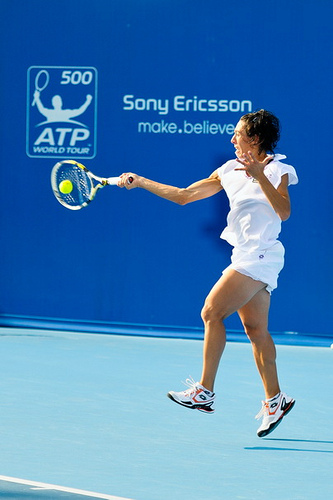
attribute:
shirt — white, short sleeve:
[204, 154, 290, 258]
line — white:
[0, 454, 126, 498]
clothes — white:
[211, 148, 300, 295]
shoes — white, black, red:
[166, 371, 293, 435]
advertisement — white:
[15, 58, 331, 175]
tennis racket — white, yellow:
[48, 156, 134, 212]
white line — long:
[1, 474, 146, 499]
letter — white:
[157, 97, 172, 117]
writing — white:
[25, 65, 250, 159]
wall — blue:
[1, 0, 332, 345]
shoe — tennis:
[164, 373, 217, 416]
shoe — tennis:
[252, 389, 297, 439]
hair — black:
[240, 107, 282, 155]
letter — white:
[172, 98, 187, 113]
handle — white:
[108, 177, 121, 186]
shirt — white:
[221, 155, 298, 250]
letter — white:
[118, 85, 137, 114]